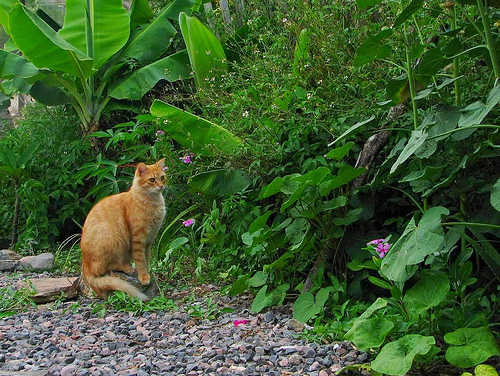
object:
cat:
[79, 157, 166, 303]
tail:
[82, 259, 149, 304]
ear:
[135, 162, 147, 172]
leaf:
[149, 99, 245, 163]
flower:
[375, 241, 391, 257]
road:
[0, 254, 380, 376]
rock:
[14, 275, 81, 306]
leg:
[131, 230, 149, 285]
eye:
[147, 177, 156, 183]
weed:
[55, 239, 209, 316]